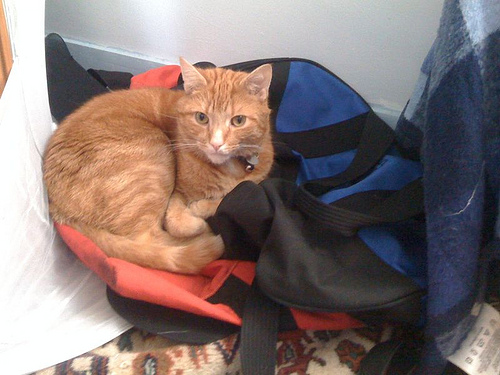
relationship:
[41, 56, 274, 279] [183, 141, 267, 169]
cat has a neck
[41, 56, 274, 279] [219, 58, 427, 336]
cat on a bag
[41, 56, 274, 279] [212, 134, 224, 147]
cat has a nose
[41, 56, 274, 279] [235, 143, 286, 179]
cat has a whisker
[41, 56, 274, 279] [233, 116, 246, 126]
cat has an eye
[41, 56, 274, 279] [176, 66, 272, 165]
cat has a head